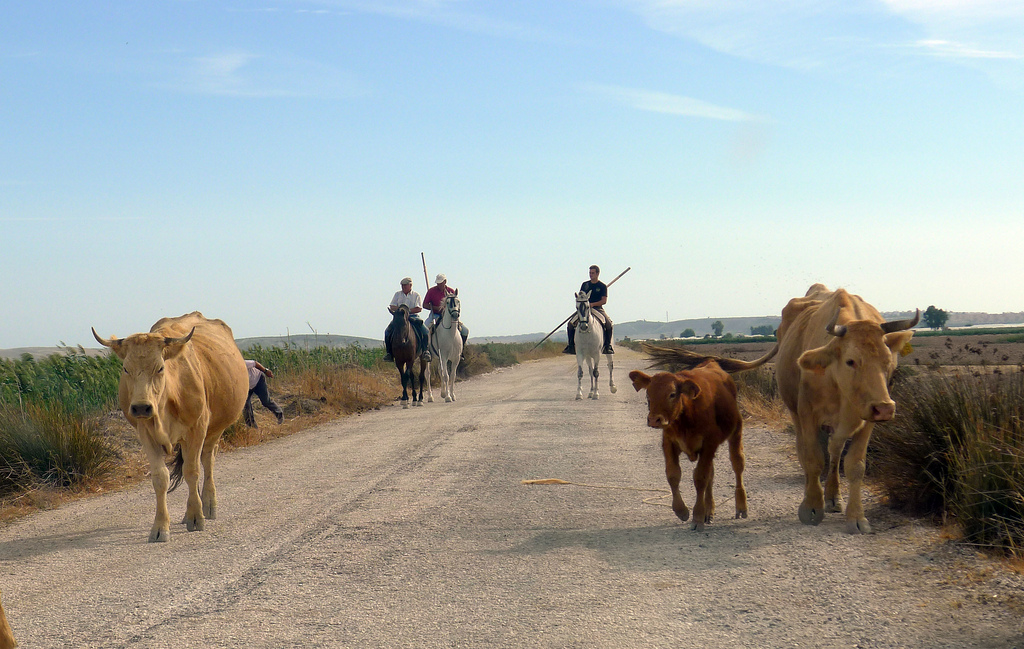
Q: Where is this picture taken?
A: On a dirt road.